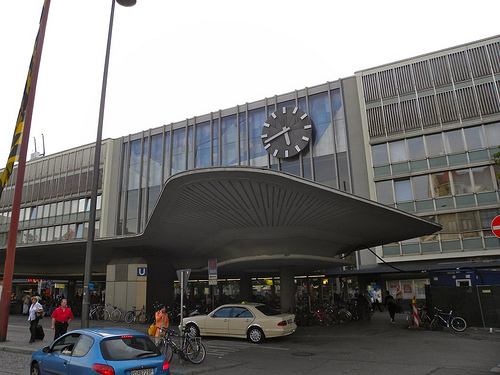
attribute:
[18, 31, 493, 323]
shopping center — large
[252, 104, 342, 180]
clock — huge, black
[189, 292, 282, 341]
car — cream-colored, yellow, white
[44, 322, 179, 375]
car — blue, one-door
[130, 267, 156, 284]
sign — blue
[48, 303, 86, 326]
shirt — red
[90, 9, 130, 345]
lightpost — silver, tall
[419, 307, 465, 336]
bike — leaning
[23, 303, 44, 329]
shirt — white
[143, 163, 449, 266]
overhang — curved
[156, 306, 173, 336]
jacket — orange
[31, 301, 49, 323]
blouse — white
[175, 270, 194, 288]
yield sign — triangular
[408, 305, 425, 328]
pole — striped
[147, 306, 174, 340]
dress — orange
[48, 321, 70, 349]
pants — black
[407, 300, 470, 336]
bikes — parked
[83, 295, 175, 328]
bikes — grouped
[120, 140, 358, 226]
windows — rectangular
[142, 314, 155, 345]
handbag — orange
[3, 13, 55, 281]
pole — brown